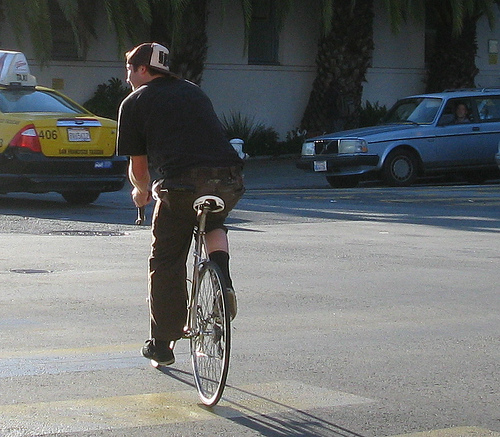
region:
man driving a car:
[431, 93, 479, 135]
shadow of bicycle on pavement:
[232, 376, 367, 432]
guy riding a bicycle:
[109, 36, 248, 411]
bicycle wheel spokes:
[192, 263, 223, 398]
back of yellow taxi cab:
[2, 81, 120, 204]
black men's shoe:
[135, 336, 177, 368]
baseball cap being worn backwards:
[117, 36, 179, 96]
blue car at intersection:
[292, 76, 498, 193]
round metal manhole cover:
[35, 222, 140, 244]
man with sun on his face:
[115, 34, 146, 94]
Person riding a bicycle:
[108, 40, 260, 416]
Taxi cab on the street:
[6, 47, 136, 232]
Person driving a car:
[435, 100, 486, 122]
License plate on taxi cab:
[60, 120, 100, 148]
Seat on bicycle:
[187, 191, 239, 223]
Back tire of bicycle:
[186, 260, 253, 416]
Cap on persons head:
[120, 35, 181, 77]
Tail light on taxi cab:
[7, 119, 53, 165]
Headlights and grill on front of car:
[295, 140, 367, 158]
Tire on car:
[382, 146, 424, 187]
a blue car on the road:
[295, 73, 498, 199]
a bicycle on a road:
[122, 179, 248, 411]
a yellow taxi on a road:
[0, 45, 133, 211]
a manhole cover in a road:
[48, 225, 120, 247]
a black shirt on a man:
[112, 74, 250, 171]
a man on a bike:
[111, 38, 247, 349]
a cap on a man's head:
[121, 41, 181, 81]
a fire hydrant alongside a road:
[227, 132, 249, 182]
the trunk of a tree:
[296, 6, 402, 146]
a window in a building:
[238, 4, 300, 72]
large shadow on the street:
[166, 367, 338, 416]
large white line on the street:
[250, 353, 395, 416]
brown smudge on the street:
[109, 387, 199, 419]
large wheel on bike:
[174, 260, 254, 399]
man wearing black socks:
[194, 230, 266, 318]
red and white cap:
[123, 34, 201, 78]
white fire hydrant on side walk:
[222, 132, 259, 165]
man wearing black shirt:
[77, 68, 264, 178]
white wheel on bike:
[185, 190, 233, 220]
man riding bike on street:
[74, 13, 299, 374]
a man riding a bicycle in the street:
[108, 35, 250, 407]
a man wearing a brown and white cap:
[115, 36, 240, 367]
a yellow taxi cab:
[0, 45, 129, 211]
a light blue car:
[291, 83, 498, 191]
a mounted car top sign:
[0, 47, 42, 89]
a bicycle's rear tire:
[182, 258, 229, 408]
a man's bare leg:
[197, 225, 230, 256]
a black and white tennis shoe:
[135, 337, 179, 372]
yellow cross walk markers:
[1, 312, 381, 432]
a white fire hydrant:
[227, 134, 249, 182]